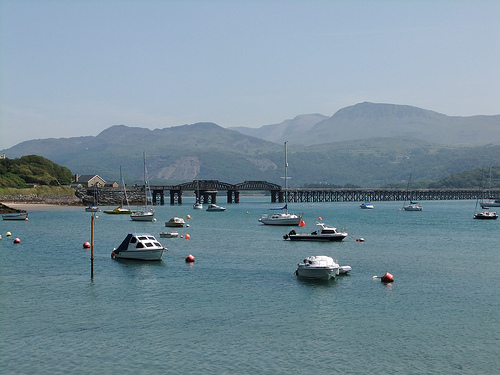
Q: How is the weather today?
A: It is cloudless.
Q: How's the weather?
A: It is cloudless.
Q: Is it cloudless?
A: Yes, it is cloudless.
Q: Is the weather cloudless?
A: Yes, it is cloudless.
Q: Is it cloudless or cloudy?
A: It is cloudless.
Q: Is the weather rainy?
A: No, it is cloudless.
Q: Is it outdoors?
A: Yes, it is outdoors.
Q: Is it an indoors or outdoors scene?
A: It is outdoors.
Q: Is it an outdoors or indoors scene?
A: It is outdoors.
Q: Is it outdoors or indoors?
A: It is outdoors.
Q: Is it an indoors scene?
A: No, it is outdoors.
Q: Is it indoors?
A: No, it is outdoors.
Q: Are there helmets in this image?
A: No, there are no helmets.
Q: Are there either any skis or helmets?
A: No, there are no helmets or skis.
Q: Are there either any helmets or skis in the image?
A: No, there are no helmets or skis.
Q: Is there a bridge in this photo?
A: Yes, there is a bridge.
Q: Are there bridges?
A: Yes, there is a bridge.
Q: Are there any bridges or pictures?
A: Yes, there is a bridge.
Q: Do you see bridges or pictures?
A: Yes, there is a bridge.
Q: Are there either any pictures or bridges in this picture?
A: Yes, there is a bridge.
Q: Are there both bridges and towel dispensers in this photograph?
A: No, there is a bridge but no towel dispensers.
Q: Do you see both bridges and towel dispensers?
A: No, there is a bridge but no towel dispensers.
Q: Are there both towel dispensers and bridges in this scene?
A: No, there is a bridge but no towel dispensers.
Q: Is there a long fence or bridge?
A: Yes, there is a long bridge.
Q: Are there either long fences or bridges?
A: Yes, there is a long bridge.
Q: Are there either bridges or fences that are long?
A: Yes, the bridge is long.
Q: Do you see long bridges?
A: Yes, there is a long bridge.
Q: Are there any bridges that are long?
A: Yes, there is a bridge that is long.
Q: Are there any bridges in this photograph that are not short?
A: Yes, there is a long bridge.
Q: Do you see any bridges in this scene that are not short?
A: Yes, there is a long bridge.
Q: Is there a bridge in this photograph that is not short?
A: Yes, there is a long bridge.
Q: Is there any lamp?
A: No, there are no lamps.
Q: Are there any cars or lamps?
A: No, there are no lamps or cars.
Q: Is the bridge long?
A: Yes, the bridge is long.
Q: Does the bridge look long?
A: Yes, the bridge is long.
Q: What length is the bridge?
A: The bridge is long.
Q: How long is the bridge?
A: The bridge is long.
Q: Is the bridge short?
A: No, the bridge is long.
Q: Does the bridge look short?
A: No, the bridge is long.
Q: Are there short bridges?
A: No, there is a bridge but it is long.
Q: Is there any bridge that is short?
A: No, there is a bridge but it is long.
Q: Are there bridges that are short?
A: No, there is a bridge but it is long.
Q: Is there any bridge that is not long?
A: No, there is a bridge but it is long.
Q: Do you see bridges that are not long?
A: No, there is a bridge but it is long.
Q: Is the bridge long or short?
A: The bridge is long.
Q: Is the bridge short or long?
A: The bridge is long.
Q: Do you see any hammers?
A: No, there are no hammers.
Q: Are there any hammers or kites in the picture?
A: No, there are no hammers or kites.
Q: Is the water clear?
A: Yes, the water is clear.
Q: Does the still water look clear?
A: Yes, the water is clear.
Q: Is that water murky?
A: No, the water is clear.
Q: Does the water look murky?
A: No, the water is clear.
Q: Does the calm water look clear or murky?
A: The water is clear.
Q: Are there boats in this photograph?
A: Yes, there is a boat.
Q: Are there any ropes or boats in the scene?
A: Yes, there is a boat.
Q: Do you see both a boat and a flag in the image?
A: No, there is a boat but no flags.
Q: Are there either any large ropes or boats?
A: Yes, there is a large boat.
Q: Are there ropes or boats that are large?
A: Yes, the boat is large.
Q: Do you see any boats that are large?
A: Yes, there is a large boat.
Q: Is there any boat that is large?
A: Yes, there is a boat that is large.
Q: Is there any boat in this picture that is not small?
A: Yes, there is a large boat.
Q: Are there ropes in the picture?
A: No, there are no ropes.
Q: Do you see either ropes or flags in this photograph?
A: No, there are no ropes or flags.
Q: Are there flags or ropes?
A: No, there are no ropes or flags.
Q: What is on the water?
A: The boat is on the water.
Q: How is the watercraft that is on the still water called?
A: The watercraft is a boat.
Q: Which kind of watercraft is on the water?
A: The watercraft is a boat.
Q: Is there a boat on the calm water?
A: Yes, there is a boat on the water.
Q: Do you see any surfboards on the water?
A: No, there is a boat on the water.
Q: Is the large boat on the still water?
A: Yes, the boat is on the water.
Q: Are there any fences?
A: No, there are no fences.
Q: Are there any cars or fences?
A: No, there are no fences or cars.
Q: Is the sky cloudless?
A: Yes, the sky is cloudless.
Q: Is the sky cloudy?
A: No, the sky is cloudless.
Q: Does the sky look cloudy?
A: No, the sky is cloudless.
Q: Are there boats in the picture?
A: Yes, there is a boat.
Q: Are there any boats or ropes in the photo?
A: Yes, there is a boat.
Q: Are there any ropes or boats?
A: Yes, there is a boat.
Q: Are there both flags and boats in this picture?
A: No, there is a boat but no flags.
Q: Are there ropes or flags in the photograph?
A: No, there are no flags or ropes.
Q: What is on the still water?
A: The boat is on the water.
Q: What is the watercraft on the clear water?
A: The watercraft is a boat.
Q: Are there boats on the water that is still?
A: Yes, there is a boat on the water.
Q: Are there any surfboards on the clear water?
A: No, there is a boat on the water.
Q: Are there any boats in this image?
A: Yes, there is a boat.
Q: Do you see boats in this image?
A: Yes, there is a boat.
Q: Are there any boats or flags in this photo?
A: Yes, there is a boat.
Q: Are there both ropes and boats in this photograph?
A: No, there is a boat but no ropes.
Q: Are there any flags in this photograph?
A: No, there are no flags.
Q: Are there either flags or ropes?
A: No, there are no flags or ropes.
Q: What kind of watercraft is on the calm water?
A: The watercraft is a boat.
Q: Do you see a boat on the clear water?
A: Yes, there is a boat on the water.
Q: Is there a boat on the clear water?
A: Yes, there is a boat on the water.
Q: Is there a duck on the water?
A: No, there is a boat on the water.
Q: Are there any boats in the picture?
A: Yes, there is a boat.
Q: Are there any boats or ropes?
A: Yes, there is a boat.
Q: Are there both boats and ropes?
A: No, there is a boat but no ropes.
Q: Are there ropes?
A: No, there are no ropes.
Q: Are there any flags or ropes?
A: No, there are no ropes or flags.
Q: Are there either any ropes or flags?
A: No, there are no ropes or flags.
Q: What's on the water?
A: The boat is on the water.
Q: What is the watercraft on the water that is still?
A: The watercraft is a boat.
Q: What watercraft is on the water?
A: The watercraft is a boat.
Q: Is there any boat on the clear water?
A: Yes, there is a boat on the water.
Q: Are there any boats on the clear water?
A: Yes, there is a boat on the water.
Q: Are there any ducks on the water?
A: No, there is a boat on the water.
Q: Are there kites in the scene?
A: No, there are no kites.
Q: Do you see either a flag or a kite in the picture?
A: No, there are no kites or flags.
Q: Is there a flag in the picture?
A: No, there are no flags.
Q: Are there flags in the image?
A: No, there are no flags.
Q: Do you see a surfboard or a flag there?
A: No, there are no flags or surfboards.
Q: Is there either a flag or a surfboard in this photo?
A: No, there are no flags or surfboards.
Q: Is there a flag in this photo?
A: No, there are no flags.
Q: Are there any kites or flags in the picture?
A: No, there are no flags or kites.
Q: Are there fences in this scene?
A: No, there are no fences.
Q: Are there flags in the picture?
A: No, there are no flags.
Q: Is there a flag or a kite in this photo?
A: No, there are no flags or kites.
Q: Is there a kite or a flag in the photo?
A: No, there are no flags or kites.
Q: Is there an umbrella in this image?
A: No, there are no umbrellas.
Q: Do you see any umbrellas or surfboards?
A: No, there are no umbrellas or surfboards.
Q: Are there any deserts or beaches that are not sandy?
A: No, there is a beach but it is sandy.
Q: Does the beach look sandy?
A: Yes, the beach is sandy.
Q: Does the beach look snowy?
A: No, the beach is sandy.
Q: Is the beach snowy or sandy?
A: The beach is sandy.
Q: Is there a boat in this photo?
A: Yes, there is a boat.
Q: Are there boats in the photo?
A: Yes, there is a boat.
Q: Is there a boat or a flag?
A: Yes, there is a boat.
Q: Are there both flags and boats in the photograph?
A: No, there is a boat but no flags.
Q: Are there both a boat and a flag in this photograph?
A: No, there is a boat but no flags.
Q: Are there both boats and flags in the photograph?
A: No, there is a boat but no flags.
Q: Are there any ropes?
A: No, there are no ropes.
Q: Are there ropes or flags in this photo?
A: No, there are no ropes or flags.